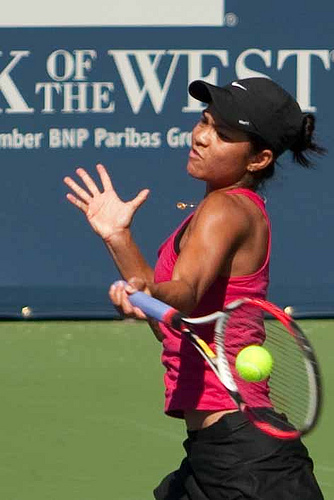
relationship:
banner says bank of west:
[3, 4, 330, 320] [1, 48, 332, 121]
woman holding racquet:
[66, 78, 322, 498] [115, 281, 319, 436]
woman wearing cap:
[66, 78, 322, 498] [188, 76, 307, 144]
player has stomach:
[66, 78, 322, 498] [181, 408, 239, 430]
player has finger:
[66, 78, 322, 498] [95, 162, 112, 193]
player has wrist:
[66, 78, 322, 498] [102, 222, 134, 247]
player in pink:
[66, 78, 322, 498] [146, 189, 272, 411]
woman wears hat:
[66, 78, 322, 498] [188, 76, 307, 144]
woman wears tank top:
[66, 78, 322, 498] [146, 189, 272, 411]